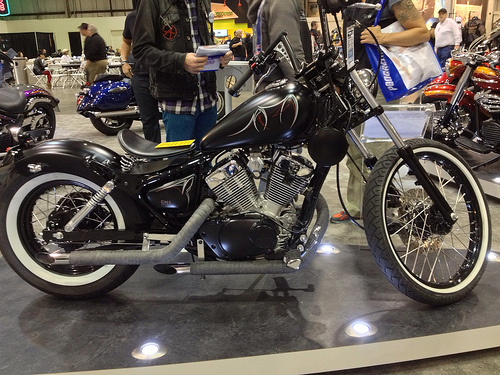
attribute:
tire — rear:
[19, 97, 62, 142]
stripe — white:
[4, 176, 33, 269]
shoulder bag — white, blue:
[359, 3, 446, 101]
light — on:
[125, 335, 172, 366]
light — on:
[338, 316, 380, 343]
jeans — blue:
[153, 97, 217, 147]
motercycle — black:
[3, 1, 490, 302]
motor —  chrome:
[205, 149, 314, 227]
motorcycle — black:
[1, 0, 488, 307]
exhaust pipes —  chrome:
[50, 191, 330, 272]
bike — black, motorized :
[0, 3, 490, 306]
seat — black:
[116, 123, 192, 157]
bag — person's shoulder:
[355, 15, 456, 103]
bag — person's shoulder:
[358, 4, 458, 126]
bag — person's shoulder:
[359, 9, 454, 119]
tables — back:
[31, 49, 150, 84]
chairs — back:
[14, 38, 55, 78]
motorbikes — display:
[29, 67, 473, 302]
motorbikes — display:
[9, 17, 478, 303]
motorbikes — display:
[12, 10, 480, 340]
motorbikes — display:
[13, 48, 482, 317]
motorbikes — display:
[4, 38, 481, 290]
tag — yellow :
[156, 140, 198, 149]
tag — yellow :
[155, 137, 195, 154]